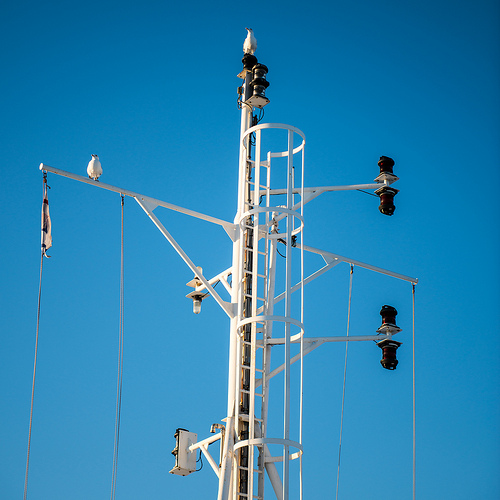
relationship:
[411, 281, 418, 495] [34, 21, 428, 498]
lines attached to tower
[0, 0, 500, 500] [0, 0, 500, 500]
clouds in blue sky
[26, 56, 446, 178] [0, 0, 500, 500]
clouds in blue sky